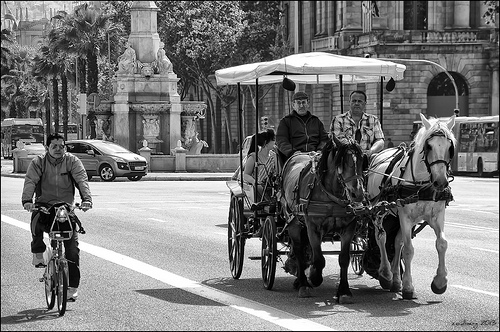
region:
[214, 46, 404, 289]
Horse-drawn carriage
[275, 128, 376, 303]
a brown and white horse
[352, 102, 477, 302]
a lightly colored horse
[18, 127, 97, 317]
Man on a bicycle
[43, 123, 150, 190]
A hatchback car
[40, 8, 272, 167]
Tall trees with leaves high at the top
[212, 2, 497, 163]
Building built with large bricks and detailed architecture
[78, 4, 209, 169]
Very detailed multi-faceted statue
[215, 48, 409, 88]
light canopy over carriage to protect passengers from sunlight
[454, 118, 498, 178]
City bus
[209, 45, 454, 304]
Old fashioned cart and horses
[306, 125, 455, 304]
One white one black horse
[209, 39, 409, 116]
Cart canopy top protecton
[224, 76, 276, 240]
Cart piled with goods rear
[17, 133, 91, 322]
Man rides bicycle along side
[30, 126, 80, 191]
Dark hair and sunglasses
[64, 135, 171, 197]
Relatively new vehicle parked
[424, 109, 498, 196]
Tourist bus parked near building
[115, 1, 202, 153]
Concrete statue figurine fountain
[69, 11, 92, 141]
Traffic light under palm trees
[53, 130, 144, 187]
a vehicle in the street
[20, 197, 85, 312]
a vehicle in the street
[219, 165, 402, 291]
a vehicle in the street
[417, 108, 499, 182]
a vehicle in the street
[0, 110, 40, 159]
a vehicle in the street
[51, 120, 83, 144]
a vehicle in the street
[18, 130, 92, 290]
a person in the street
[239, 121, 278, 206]
a person in the street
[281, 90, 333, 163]
a person in the street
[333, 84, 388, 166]
a person in the street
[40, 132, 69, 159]
the head of a person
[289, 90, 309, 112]
the head of a person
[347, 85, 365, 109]
the head of a person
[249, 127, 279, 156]
the head of a person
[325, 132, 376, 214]
the head of a horse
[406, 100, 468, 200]
the head of a horse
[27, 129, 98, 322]
a guy riding a bike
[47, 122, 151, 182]
a car on the street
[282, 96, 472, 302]
two horses carrying a cart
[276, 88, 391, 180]
two men in a cart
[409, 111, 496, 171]
bus in right side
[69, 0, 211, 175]
architectural monument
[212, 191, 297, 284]
two wheels at the right of the cart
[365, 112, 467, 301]
white horse alongside the black horse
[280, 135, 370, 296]
black horse alongside the white horse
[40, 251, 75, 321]
wheels of the bike